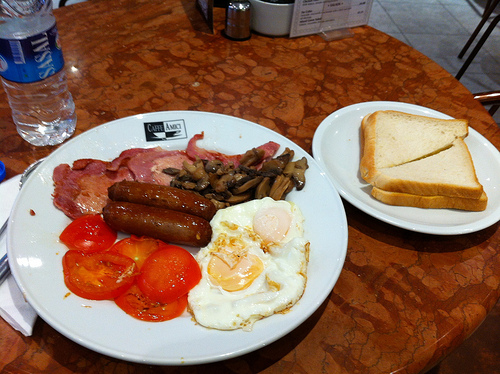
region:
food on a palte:
[12, 79, 319, 346]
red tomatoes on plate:
[47, 241, 138, 305]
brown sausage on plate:
[82, 178, 222, 250]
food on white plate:
[44, 125, 281, 297]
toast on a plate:
[361, 98, 483, 258]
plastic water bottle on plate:
[0, 29, 92, 144]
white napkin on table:
[2, 308, 40, 339]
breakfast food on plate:
[97, 113, 311, 334]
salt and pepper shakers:
[202, 2, 257, 46]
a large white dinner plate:
[11, 108, 350, 364]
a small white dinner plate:
[310, 99, 499, 233]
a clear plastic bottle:
[2, 0, 76, 147]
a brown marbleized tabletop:
[5, 2, 498, 370]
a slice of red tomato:
[63, 246, 136, 299]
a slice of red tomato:
[61, 212, 114, 250]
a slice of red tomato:
[138, 241, 200, 299]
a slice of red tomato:
[117, 283, 187, 321]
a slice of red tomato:
[110, 233, 166, 271]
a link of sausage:
[100, 201, 212, 249]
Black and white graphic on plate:
[141, 119, 189, 145]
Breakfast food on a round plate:
[5, 106, 346, 363]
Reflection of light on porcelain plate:
[10, 242, 44, 276]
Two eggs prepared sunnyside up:
[190, 194, 307, 334]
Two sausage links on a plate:
[105, 176, 215, 256]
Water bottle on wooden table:
[0, 4, 82, 151]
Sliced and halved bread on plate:
[316, 99, 498, 236]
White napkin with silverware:
[1, 153, 63, 341]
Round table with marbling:
[0, 5, 492, 372]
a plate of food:
[25, 86, 279, 371]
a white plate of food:
[42, 97, 268, 372]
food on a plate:
[54, 111, 283, 361]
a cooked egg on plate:
[204, 211, 294, 339]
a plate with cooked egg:
[178, 188, 337, 353]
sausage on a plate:
[116, 165, 213, 269]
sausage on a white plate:
[101, 137, 249, 276]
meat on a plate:
[64, 123, 231, 185]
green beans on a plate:
[149, 126, 324, 235]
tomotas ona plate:
[51, 205, 206, 351]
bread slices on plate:
[361, 104, 486, 216]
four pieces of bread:
[354, 107, 489, 214]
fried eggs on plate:
[192, 199, 312, 328]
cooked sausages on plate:
[105, 184, 216, 246]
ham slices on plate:
[48, 132, 283, 216]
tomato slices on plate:
[63, 212, 200, 323]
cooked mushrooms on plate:
[164, 149, 309, 203]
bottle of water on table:
[2, 2, 78, 147]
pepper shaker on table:
[224, 2, 254, 42]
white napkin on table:
[1, 170, 37, 340]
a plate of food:
[20, 111, 355, 363]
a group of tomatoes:
[54, 212, 199, 329]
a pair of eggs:
[185, 197, 317, 337]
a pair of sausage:
[91, 173, 214, 250]